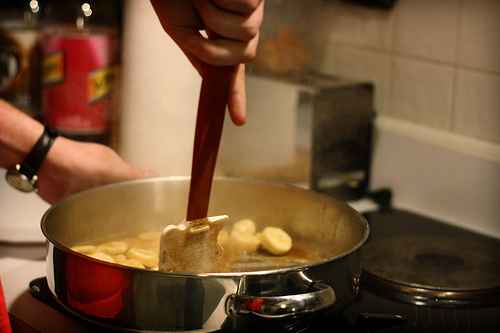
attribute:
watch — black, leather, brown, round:
[6, 125, 58, 194]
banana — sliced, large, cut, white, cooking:
[67, 219, 291, 272]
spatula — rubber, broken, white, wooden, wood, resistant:
[159, 64, 234, 274]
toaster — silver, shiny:
[213, 69, 378, 201]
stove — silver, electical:
[28, 209, 499, 332]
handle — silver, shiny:
[226, 280, 337, 320]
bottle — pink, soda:
[42, 0, 124, 147]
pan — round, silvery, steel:
[41, 174, 370, 331]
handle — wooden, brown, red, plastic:
[186, 66, 236, 221]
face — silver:
[6, 174, 35, 194]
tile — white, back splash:
[245, 0, 498, 147]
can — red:
[40, 28, 120, 138]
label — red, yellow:
[40, 25, 122, 136]